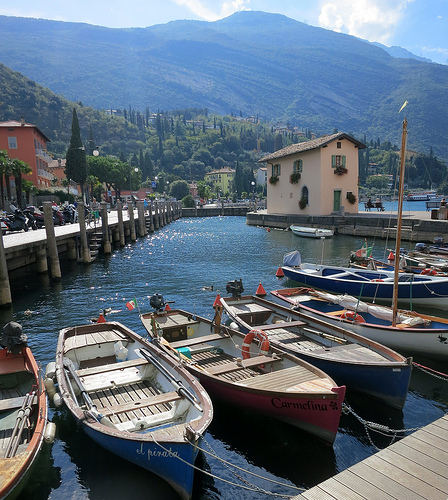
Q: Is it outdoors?
A: Yes, it is outdoors.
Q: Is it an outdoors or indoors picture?
A: It is outdoors.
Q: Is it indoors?
A: No, it is outdoors.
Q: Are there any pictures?
A: No, there are no pictures.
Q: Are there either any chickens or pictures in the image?
A: No, there are no pictures or chickens.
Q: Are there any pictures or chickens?
A: No, there are no pictures or chickens.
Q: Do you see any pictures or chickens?
A: No, there are no pictures or chickens.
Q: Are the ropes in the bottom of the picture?
A: Yes, the ropes are in the bottom of the image.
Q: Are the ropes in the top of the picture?
A: No, the ropes are in the bottom of the image.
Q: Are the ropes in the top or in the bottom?
A: The ropes are in the bottom of the image.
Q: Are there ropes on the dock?
A: Yes, there are ropes on the dock.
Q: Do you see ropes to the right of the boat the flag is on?
A: Yes, there are ropes to the right of the boat.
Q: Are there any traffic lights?
A: No, there are no traffic lights.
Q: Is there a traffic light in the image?
A: No, there are no traffic lights.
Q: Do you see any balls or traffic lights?
A: No, there are no traffic lights or balls.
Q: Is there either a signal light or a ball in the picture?
A: No, there are no traffic lights or balls.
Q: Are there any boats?
A: Yes, there is a boat.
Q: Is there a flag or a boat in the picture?
A: Yes, there is a boat.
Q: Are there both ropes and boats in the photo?
A: Yes, there are both a boat and a rope.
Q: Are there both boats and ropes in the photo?
A: Yes, there are both a boat and a rope.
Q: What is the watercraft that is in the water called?
A: The watercraft is a boat.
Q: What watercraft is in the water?
A: The watercraft is a boat.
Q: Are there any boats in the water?
A: Yes, there is a boat in the water.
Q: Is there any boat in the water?
A: Yes, there is a boat in the water.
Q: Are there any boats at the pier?
A: Yes, there is a boat at the pier.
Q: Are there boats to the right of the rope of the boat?
A: No, the boat is to the left of the rope.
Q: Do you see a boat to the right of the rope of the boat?
A: No, the boat is to the left of the rope.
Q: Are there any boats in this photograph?
A: Yes, there is a boat.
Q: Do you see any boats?
A: Yes, there is a boat.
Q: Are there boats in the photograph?
A: Yes, there is a boat.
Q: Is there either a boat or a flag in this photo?
A: Yes, there is a boat.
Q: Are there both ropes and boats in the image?
A: Yes, there are both a boat and a rope.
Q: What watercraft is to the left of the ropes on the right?
A: The watercraft is a boat.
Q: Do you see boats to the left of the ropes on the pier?
A: Yes, there is a boat to the left of the ropes.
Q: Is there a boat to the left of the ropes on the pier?
A: Yes, there is a boat to the left of the ropes.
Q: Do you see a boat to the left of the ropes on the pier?
A: Yes, there is a boat to the left of the ropes.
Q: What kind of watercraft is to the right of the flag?
A: The watercraft is a boat.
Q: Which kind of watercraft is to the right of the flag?
A: The watercraft is a boat.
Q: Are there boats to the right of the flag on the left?
A: Yes, there is a boat to the right of the flag.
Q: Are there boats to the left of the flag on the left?
A: No, the boat is to the right of the flag.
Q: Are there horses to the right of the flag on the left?
A: No, there is a boat to the right of the flag.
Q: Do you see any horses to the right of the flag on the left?
A: No, there is a boat to the right of the flag.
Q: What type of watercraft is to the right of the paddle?
A: The watercraft is a boat.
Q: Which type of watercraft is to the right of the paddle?
A: The watercraft is a boat.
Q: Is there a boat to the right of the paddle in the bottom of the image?
A: Yes, there is a boat to the right of the oar.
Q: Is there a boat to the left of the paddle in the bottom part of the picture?
A: No, the boat is to the right of the paddle.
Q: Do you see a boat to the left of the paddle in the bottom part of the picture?
A: No, the boat is to the right of the paddle.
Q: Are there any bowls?
A: No, there are no bowls.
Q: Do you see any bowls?
A: No, there are no bowls.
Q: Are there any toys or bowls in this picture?
A: No, there are no bowls or toys.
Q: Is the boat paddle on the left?
A: Yes, the paddle is on the left of the image.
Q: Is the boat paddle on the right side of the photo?
A: No, the paddle is on the left of the image.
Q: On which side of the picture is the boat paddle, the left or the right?
A: The oar is on the left of the image.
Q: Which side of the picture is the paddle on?
A: The paddle is on the left of the image.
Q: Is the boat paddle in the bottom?
A: Yes, the oar is in the bottom of the image.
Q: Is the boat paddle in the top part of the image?
A: No, the oar is in the bottom of the image.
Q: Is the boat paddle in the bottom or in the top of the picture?
A: The oar is in the bottom of the image.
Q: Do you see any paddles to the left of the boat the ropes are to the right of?
A: Yes, there is a paddle to the left of the boat.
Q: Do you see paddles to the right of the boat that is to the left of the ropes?
A: No, the paddle is to the left of the boat.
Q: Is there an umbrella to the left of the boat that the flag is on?
A: No, there is a paddle to the left of the boat.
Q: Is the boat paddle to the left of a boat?
A: Yes, the paddle is to the left of a boat.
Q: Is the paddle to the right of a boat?
A: No, the paddle is to the left of a boat.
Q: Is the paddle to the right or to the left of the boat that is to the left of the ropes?
A: The paddle is to the left of the boat.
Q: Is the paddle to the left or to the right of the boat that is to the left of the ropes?
A: The paddle is to the left of the boat.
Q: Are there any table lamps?
A: No, there are no table lamps.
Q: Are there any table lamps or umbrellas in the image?
A: No, there are no table lamps or umbrellas.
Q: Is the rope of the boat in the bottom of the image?
A: Yes, the rope is in the bottom of the image.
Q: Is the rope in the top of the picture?
A: No, the rope is in the bottom of the image.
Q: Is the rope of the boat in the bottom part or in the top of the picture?
A: The rope is in the bottom of the image.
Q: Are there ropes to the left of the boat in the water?
A: No, the rope is to the right of the boat.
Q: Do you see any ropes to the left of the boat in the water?
A: No, the rope is to the right of the boat.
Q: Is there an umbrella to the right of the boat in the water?
A: No, there is a rope to the right of the boat.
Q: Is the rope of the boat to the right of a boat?
A: Yes, the rope is to the right of a boat.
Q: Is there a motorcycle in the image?
A: Yes, there is a motorcycle.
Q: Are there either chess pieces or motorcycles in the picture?
A: Yes, there is a motorcycle.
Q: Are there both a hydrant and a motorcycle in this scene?
A: No, there is a motorcycle but no fire hydrants.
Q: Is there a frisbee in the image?
A: No, there are no frisbees.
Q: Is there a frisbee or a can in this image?
A: No, there are no frisbees or cans.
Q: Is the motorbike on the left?
A: Yes, the motorbike is on the left of the image.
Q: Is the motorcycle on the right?
A: No, the motorcycle is on the left of the image.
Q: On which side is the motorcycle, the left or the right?
A: The motorcycle is on the left of the image.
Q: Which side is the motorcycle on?
A: The motorcycle is on the left of the image.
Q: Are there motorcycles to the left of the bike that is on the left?
A: Yes, there is a motorcycle to the left of the bike.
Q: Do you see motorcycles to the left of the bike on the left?
A: Yes, there is a motorcycle to the left of the bike.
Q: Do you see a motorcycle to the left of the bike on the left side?
A: Yes, there is a motorcycle to the left of the bike.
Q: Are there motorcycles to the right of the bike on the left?
A: No, the motorcycle is to the left of the bike.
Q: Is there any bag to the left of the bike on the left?
A: No, there is a motorcycle to the left of the bike.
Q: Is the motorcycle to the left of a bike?
A: Yes, the motorcycle is to the left of a bike.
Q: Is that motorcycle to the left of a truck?
A: No, the motorcycle is to the left of a bike.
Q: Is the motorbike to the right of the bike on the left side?
A: No, the motorbike is to the left of the bike.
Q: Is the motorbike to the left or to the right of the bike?
A: The motorbike is to the left of the bike.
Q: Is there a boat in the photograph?
A: Yes, there is a boat.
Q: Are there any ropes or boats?
A: Yes, there is a boat.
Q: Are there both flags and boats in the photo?
A: Yes, there are both a boat and a flag.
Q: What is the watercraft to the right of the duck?
A: The watercraft is a boat.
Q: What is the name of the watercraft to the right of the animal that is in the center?
A: The watercraft is a boat.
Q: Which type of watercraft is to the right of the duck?
A: The watercraft is a boat.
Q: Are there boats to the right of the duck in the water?
A: Yes, there is a boat to the right of the duck.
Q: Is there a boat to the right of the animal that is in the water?
A: Yes, there is a boat to the right of the duck.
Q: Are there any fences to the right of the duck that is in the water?
A: No, there is a boat to the right of the duck.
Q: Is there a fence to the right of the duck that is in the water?
A: No, there is a boat to the right of the duck.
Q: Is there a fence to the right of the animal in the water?
A: No, there is a boat to the right of the duck.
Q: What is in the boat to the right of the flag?
A: The life preserver is in the boat.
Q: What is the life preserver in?
A: The life preserver is in the boat.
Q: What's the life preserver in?
A: The life preserver is in the boat.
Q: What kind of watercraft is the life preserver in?
A: The life preserver is in the boat.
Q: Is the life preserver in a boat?
A: Yes, the life preserver is in a boat.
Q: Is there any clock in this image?
A: No, there are no clocks.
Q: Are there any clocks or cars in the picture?
A: No, there are no clocks or cars.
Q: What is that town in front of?
A: The town is in front of the mountain.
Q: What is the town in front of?
A: The town is in front of the mountain.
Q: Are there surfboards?
A: No, there are no surfboards.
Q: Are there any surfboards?
A: No, there are no surfboards.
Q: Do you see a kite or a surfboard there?
A: No, there are no surfboards or kites.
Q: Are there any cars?
A: No, there are no cars.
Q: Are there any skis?
A: No, there are no skis.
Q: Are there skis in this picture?
A: No, there are no skis.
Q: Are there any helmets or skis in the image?
A: No, there are no skis or helmets.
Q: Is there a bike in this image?
A: Yes, there is a bike.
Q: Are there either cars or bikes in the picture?
A: Yes, there is a bike.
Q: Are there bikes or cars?
A: Yes, there is a bike.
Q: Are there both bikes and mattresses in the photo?
A: No, there is a bike but no mattresses.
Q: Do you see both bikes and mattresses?
A: No, there is a bike but no mattresses.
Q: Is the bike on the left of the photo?
A: Yes, the bike is on the left of the image.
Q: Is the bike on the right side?
A: No, the bike is on the left of the image.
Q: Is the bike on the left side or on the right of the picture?
A: The bike is on the left of the image.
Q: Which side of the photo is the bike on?
A: The bike is on the left of the image.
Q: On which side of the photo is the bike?
A: The bike is on the left of the image.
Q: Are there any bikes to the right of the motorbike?
A: Yes, there is a bike to the right of the motorbike.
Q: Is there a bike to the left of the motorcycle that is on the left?
A: No, the bike is to the right of the motorcycle.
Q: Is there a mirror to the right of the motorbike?
A: No, there is a bike to the right of the motorbike.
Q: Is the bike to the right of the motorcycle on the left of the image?
A: Yes, the bike is to the right of the motorcycle.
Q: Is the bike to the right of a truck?
A: No, the bike is to the right of the motorcycle.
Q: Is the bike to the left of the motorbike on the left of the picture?
A: No, the bike is to the right of the motorcycle.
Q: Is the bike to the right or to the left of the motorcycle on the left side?
A: The bike is to the right of the motorbike.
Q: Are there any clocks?
A: No, there are no clocks.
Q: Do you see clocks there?
A: No, there are no clocks.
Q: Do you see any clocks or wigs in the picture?
A: No, there are no clocks or wigs.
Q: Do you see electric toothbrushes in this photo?
A: No, there are no electric toothbrushes.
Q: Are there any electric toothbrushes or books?
A: No, there are no electric toothbrushes or books.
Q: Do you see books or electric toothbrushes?
A: No, there are no electric toothbrushes or books.